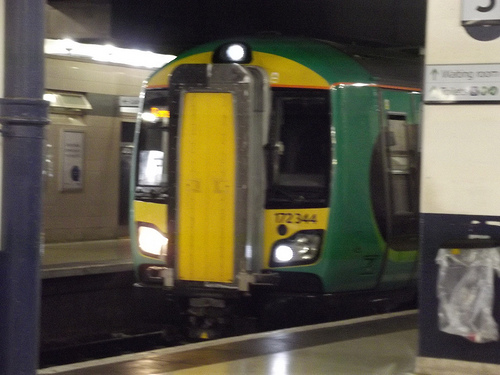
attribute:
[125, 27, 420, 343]
train — green, gray, yellow, white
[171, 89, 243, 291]
door — yellow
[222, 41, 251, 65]
light — white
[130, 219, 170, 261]
light — white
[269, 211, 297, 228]
number — black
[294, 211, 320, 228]
number — black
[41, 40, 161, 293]
wall — tan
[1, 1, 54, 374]
pole — blue, metal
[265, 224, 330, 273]
headlight — off